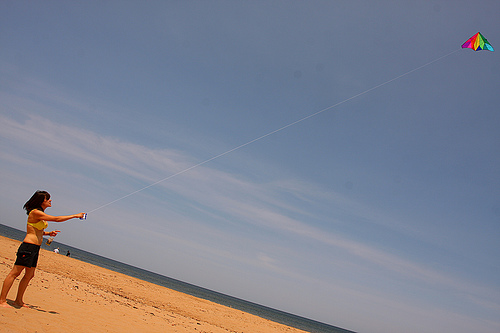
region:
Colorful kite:
[459, 32, 493, 54]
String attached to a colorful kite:
[80, 45, 467, 219]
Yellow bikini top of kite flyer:
[26, 217, 51, 232]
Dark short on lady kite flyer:
[13, 241, 41, 267]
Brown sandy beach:
[1, 232, 306, 331]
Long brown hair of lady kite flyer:
[23, 189, 50, 217]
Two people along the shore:
[47, 243, 77, 258]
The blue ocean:
[1, 221, 357, 331]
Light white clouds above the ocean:
[1, 101, 498, 311]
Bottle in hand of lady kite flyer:
[41, 228, 59, 250]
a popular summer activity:
[29, 18, 492, 319]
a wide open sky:
[46, 25, 428, 289]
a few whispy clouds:
[173, 114, 423, 285]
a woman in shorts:
[0, 164, 110, 310]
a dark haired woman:
[5, 178, 91, 300]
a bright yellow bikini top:
[22, 207, 55, 247]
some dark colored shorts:
[4, 231, 48, 278]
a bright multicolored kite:
[460, 18, 498, 80]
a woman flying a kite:
[13, 14, 498, 320]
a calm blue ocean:
[86, 246, 200, 318]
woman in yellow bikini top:
[3, 175, 82, 325]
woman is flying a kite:
[3, 167, 65, 331]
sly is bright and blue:
[136, 83, 483, 310]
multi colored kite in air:
[452, 28, 494, 55]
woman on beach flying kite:
[3, 180, 85, 311]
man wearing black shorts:
[10, 239, 42, 266]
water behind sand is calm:
[1, 221, 363, 332]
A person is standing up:
[15, 185, 70, 309]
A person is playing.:
[13, 184, 53, 310]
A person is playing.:
[66, 248, 71, 256]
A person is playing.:
[54, 243, 58, 252]